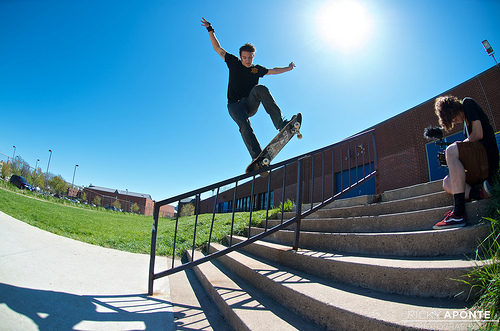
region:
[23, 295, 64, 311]
Shadow on the ground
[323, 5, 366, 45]
Sun shining in the sky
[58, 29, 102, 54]
A clear blue sky above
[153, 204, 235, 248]
The bluish metal rail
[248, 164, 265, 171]
Skating on the rail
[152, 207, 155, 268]
The bar running downwards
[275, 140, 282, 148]
The bottom of the skate board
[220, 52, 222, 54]
A tattoo in the arm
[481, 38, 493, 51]
A lamp on the roof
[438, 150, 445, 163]
A camera in front of the knee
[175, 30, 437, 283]
This is a teenager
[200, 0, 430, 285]
This is a man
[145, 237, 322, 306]
This is a staircase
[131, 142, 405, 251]
This is a railing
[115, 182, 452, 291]
The railing is black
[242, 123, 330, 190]
This is a skateboard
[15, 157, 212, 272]
This is a building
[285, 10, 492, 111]
The sun is shining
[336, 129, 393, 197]
This is a sign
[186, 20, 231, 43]
This is a bracelet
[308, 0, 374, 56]
A bright sun in the sky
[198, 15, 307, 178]
A skateboarder is in the air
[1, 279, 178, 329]
Shadows cast on the pavement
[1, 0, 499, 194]
A clear and bright blue sky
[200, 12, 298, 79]
Skateboarder has his two arms raised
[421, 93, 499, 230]
A person sitting on the stairs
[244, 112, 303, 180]
A skateboard under the guy's feet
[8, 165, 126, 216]
Vehicles parked in a parking lot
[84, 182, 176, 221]
A brown building in the background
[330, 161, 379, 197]
A window on the side of a building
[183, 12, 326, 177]
the youth is on a skate board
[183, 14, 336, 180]
he is grinding on the railing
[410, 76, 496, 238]
the boy is sitting on the stairs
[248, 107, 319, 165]
the bottom of the skate board is black and white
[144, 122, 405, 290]
the railing is black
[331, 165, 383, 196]
the doors to the school are blue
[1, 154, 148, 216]
a fence separates the school from the parking lot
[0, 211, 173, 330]
a cement sidewalk leads up to the stairs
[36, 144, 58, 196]
street lights are in the parking lot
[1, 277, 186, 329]
the skateboarders shadow is on the sidewalk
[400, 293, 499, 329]
a watermark in the lower right corner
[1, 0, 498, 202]
a blue sky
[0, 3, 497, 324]
a scene during the day time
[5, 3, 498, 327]
a scene outside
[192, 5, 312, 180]
a man skateboarding doing a trick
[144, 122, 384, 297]
a person sliding down a rail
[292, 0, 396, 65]
a bright sun in the sky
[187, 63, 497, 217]
a brick building in the background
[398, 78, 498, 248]
a person sitting on the steps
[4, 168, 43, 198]
a black vehicle in the distance